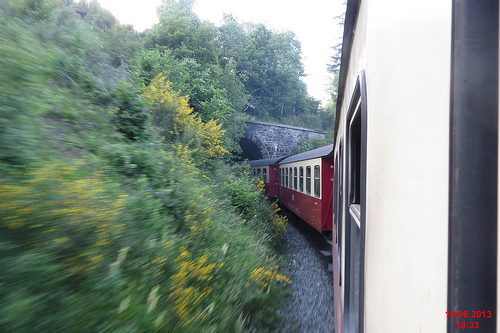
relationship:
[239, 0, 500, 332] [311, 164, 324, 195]
train with window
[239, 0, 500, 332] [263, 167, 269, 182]
train with window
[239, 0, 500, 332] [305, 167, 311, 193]
train with window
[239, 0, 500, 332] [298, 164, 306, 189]
train with window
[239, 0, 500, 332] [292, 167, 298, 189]
train with window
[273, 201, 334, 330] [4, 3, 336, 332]
gravel on ground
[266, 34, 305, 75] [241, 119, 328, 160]
tree over bridge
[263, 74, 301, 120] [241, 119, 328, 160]
tree over bridge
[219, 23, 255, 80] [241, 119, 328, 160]
tree over bridge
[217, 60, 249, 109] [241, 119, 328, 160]
tree over bridge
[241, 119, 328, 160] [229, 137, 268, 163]
bridge over tunnel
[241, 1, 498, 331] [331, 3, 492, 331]
train has caboose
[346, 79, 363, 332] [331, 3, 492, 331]
window on caboose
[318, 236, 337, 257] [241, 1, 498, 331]
step protrudes from train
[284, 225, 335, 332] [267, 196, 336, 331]
gravel alongside railway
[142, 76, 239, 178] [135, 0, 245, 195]
flowers within trees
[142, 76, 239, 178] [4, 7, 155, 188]
flowers within shrubbery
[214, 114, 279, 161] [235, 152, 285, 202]
tunnel over railroad car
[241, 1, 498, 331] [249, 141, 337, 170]
train has roof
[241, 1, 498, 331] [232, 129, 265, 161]
train out tunnel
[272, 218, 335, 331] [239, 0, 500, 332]
rocks along train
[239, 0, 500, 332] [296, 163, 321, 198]
train has window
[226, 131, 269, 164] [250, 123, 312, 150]
tunnel has bricks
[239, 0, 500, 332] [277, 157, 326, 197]
train has windows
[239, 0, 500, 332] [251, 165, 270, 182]
train has windows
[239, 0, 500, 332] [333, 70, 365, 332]
train has windows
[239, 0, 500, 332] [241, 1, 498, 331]
train on train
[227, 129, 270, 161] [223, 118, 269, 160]
arch of tunnel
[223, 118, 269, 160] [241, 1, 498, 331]
tunnel of train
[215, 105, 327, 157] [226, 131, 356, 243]
bridge over train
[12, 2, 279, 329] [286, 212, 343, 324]
bushes next to track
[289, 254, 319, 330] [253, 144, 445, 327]
gravel next to track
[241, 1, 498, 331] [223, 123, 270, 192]
train entering tunnel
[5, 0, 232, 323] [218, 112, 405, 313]
hillside next to track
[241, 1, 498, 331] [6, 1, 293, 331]
train traveling through forestry area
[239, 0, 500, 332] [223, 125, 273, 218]
train going through tunnel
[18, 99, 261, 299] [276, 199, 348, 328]
shrubbery next to railway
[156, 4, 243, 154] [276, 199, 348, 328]
trees next to railway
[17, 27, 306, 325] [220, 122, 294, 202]
trees above tunnel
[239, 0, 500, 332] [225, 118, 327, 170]
train entering tunnel